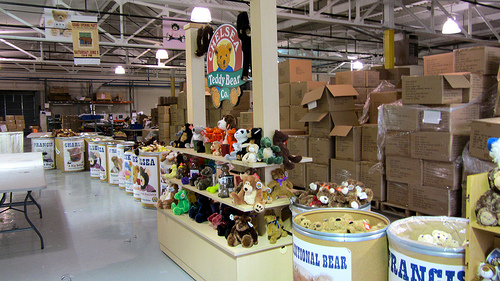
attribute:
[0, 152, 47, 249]
table — empty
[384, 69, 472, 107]
box — opened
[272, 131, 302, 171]
stuffed animal — brown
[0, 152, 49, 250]
folding table — white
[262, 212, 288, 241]
bear — golden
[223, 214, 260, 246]
teddy bear — brown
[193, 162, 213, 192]
teddy bear — brown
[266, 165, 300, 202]
teddy bear — brown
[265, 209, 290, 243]
teddy bear — brown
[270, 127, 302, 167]
teddy bear — brown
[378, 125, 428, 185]
boxes — brown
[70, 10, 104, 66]
banner — brown, white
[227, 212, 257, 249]
stuffed animal — brown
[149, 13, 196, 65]
banner — pink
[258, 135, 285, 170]
animal — green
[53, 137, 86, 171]
barrel — filled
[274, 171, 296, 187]
ribbon — purple